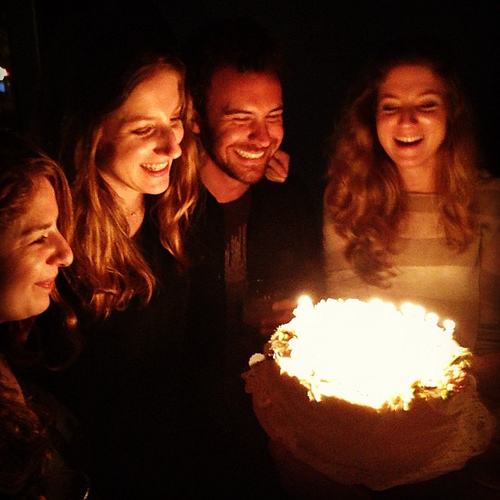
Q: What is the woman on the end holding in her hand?
A: A birthday cake.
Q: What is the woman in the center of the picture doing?
A: Holding the man's neck.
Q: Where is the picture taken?
A: In a dark room.